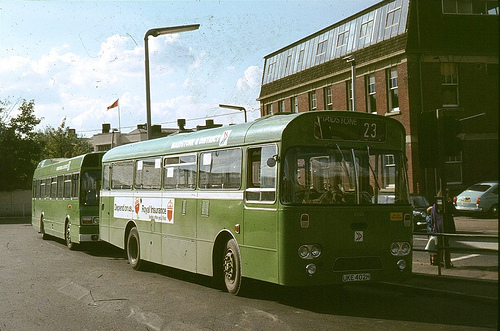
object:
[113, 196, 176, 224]
banner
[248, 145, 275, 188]
windows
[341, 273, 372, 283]
license plate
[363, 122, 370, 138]
number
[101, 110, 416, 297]
bus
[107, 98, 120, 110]
flag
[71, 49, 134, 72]
distance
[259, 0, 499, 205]
building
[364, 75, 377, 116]
windows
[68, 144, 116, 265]
each other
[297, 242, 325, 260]
headlights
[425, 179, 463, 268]
person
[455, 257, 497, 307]
sidewalk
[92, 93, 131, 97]
wind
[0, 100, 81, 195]
trees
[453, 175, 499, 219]
little car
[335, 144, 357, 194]
wipers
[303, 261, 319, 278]
lights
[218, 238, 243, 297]
wheel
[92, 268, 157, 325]
road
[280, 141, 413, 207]
windshield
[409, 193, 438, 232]
car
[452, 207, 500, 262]
road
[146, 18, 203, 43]
light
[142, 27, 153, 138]
pole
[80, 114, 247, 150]
buildings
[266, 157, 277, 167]
mirror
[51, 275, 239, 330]
design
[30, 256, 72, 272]
concrete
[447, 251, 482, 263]
line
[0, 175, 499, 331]
lot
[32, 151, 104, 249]
bus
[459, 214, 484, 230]
street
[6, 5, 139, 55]
sky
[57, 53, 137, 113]
white clouds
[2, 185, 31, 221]
fence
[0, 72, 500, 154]
background